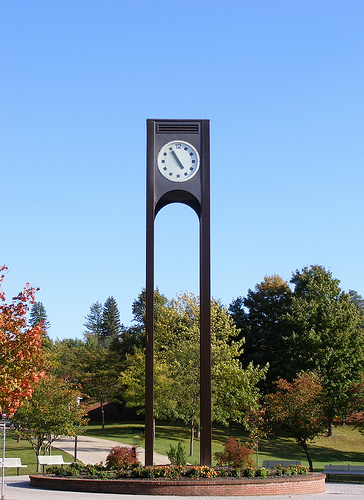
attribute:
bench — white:
[37, 453, 72, 472]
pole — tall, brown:
[195, 208, 214, 465]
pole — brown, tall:
[142, 212, 156, 464]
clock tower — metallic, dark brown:
[136, 113, 216, 476]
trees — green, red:
[2, 253, 362, 440]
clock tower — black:
[143, 116, 209, 200]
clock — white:
[152, 134, 207, 183]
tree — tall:
[247, 249, 359, 488]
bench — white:
[262, 455, 300, 472]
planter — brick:
[28, 472, 325, 494]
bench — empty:
[30, 449, 70, 467]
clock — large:
[142, 117, 212, 466]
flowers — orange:
[162, 456, 225, 478]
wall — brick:
[141, 468, 286, 486]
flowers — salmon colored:
[146, 454, 202, 467]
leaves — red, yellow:
[30, 329, 40, 339]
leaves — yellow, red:
[1, 309, 14, 326]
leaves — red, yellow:
[298, 378, 308, 386]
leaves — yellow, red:
[224, 449, 233, 457]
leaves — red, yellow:
[124, 452, 134, 458]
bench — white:
[0, 449, 29, 479]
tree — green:
[278, 260, 362, 433]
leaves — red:
[6, 316, 27, 369]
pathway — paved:
[35, 431, 193, 466]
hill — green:
[1, 422, 362, 471]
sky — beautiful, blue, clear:
[2, 1, 362, 340]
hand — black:
[171, 148, 178, 161]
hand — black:
[178, 159, 184, 170]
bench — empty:
[324, 464, 361, 487]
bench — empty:
[262, 458, 301, 473]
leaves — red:
[2, 252, 52, 421]